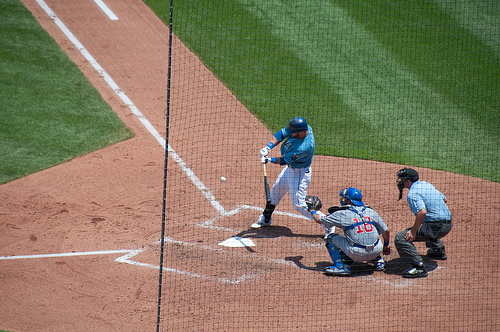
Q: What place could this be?
A: It is a field.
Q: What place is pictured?
A: It is a field.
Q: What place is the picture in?
A: It is at the field.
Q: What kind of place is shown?
A: It is a field.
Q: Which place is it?
A: It is a field.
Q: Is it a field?
A: Yes, it is a field.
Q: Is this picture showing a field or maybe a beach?
A: It is showing a field.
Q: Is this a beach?
A: No, it is a field.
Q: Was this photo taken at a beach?
A: No, the picture was taken in a field.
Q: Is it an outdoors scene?
A: Yes, it is outdoors.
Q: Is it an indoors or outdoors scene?
A: It is outdoors.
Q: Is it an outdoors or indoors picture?
A: It is outdoors.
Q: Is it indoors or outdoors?
A: It is outdoors.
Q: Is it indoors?
A: No, it is outdoors.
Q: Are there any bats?
A: Yes, there is a bat.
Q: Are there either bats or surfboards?
A: Yes, there is a bat.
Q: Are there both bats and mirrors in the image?
A: No, there is a bat but no mirrors.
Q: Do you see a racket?
A: No, there are no rackets.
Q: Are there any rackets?
A: No, there are no rackets.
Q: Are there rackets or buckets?
A: No, there are no rackets or buckets.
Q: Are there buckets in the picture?
A: No, there are no buckets.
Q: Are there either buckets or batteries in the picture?
A: No, there are no buckets or batteries.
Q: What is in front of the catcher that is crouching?
A: The home plate is in front of the catcher.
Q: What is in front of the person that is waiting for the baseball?
A: The home plate is in front of the catcher.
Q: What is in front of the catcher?
A: The home plate is in front of the catcher.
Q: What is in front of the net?
A: The home plate is in front of the net.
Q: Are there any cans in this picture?
A: No, there are no cans.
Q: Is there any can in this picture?
A: No, there are no cans.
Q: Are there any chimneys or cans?
A: No, there are no cans or chimneys.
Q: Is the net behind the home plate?
A: Yes, the net is behind the home plate.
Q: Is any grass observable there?
A: Yes, there is grass.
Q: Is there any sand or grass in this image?
A: Yes, there is grass.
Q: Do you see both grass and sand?
A: No, there is grass but no sand.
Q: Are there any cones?
A: No, there are no cones.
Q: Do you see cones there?
A: No, there are no cones.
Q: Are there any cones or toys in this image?
A: No, there are no cones or toys.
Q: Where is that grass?
A: The grass is in the field.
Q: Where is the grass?
A: The grass is in the field.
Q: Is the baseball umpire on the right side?
A: Yes, the umpire is on the right of the image.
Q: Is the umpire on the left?
A: No, the umpire is on the right of the image.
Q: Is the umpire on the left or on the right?
A: The umpire is on the right of the image.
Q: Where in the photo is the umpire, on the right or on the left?
A: The umpire is on the right of the image.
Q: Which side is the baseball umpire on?
A: The umpire is on the right of the image.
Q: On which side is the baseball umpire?
A: The umpire is on the right of the image.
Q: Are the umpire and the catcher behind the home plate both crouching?
A: Yes, both the umpire and the catcher are crouching.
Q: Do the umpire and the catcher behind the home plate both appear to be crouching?
A: Yes, both the umpire and the catcher are crouching.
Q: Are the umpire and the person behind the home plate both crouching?
A: Yes, both the umpire and the catcher are crouching.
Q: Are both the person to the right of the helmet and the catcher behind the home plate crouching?
A: Yes, both the umpire and the catcher are crouching.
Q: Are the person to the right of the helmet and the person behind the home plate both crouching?
A: Yes, both the umpire and the catcher are crouching.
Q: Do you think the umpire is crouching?
A: Yes, the umpire is crouching.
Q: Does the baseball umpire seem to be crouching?
A: Yes, the umpire is crouching.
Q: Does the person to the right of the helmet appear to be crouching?
A: Yes, the umpire is crouching.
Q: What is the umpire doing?
A: The umpire is crouching.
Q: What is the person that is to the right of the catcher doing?
A: The umpire is crouching.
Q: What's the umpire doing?
A: The umpire is crouching.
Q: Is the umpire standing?
A: No, the umpire is crouching.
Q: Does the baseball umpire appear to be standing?
A: No, the umpire is crouching.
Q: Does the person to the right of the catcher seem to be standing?
A: No, the umpire is crouching.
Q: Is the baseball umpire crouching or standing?
A: The umpire is crouching.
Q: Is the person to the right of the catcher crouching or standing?
A: The umpire is crouching.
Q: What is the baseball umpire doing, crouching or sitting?
A: The umpire is crouching.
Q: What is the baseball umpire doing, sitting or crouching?
A: The umpire is crouching.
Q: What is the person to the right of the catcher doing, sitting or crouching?
A: The umpire is crouching.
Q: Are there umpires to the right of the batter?
A: Yes, there is an umpire to the right of the batter.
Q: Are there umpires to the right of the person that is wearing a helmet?
A: Yes, there is an umpire to the right of the batter.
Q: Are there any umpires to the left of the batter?
A: No, the umpire is to the right of the batter.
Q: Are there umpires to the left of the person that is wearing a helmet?
A: No, the umpire is to the right of the batter.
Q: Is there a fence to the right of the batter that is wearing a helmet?
A: No, there is an umpire to the right of the batter.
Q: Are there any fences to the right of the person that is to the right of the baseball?
A: No, there is an umpire to the right of the batter.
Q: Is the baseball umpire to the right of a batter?
A: Yes, the umpire is to the right of a batter.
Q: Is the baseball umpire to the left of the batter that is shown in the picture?
A: No, the umpire is to the right of the batter.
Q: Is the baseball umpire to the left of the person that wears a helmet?
A: No, the umpire is to the right of the batter.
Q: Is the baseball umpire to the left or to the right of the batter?
A: The umpire is to the right of the batter.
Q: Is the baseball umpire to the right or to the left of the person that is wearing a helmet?
A: The umpire is to the right of the batter.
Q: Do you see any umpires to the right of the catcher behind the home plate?
A: Yes, there is an umpire to the right of the catcher.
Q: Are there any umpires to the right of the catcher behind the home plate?
A: Yes, there is an umpire to the right of the catcher.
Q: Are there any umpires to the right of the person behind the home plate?
A: Yes, there is an umpire to the right of the catcher.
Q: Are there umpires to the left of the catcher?
A: No, the umpire is to the right of the catcher.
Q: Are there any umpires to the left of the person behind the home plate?
A: No, the umpire is to the right of the catcher.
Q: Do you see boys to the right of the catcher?
A: No, there is an umpire to the right of the catcher.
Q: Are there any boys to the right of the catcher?
A: No, there is an umpire to the right of the catcher.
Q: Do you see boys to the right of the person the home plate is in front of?
A: No, there is an umpire to the right of the catcher.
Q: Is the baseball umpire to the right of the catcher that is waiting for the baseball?
A: Yes, the umpire is to the right of the catcher.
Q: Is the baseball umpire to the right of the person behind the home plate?
A: Yes, the umpire is to the right of the catcher.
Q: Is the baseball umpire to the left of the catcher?
A: No, the umpire is to the right of the catcher.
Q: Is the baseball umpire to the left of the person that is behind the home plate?
A: No, the umpire is to the right of the catcher.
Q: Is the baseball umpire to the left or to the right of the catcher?
A: The umpire is to the right of the catcher.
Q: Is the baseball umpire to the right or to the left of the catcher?
A: The umpire is to the right of the catcher.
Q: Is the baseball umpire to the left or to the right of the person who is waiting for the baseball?
A: The umpire is to the right of the catcher.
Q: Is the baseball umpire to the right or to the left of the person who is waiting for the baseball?
A: The umpire is to the right of the catcher.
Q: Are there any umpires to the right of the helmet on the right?
A: Yes, there is an umpire to the right of the helmet.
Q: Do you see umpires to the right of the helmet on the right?
A: Yes, there is an umpire to the right of the helmet.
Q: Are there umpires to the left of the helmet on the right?
A: No, the umpire is to the right of the helmet.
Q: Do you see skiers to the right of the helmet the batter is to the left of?
A: No, there is an umpire to the right of the helmet.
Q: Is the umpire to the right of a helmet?
A: Yes, the umpire is to the right of a helmet.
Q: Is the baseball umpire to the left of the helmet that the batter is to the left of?
A: No, the umpire is to the right of the helmet.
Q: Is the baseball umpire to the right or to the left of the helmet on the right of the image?
A: The umpire is to the right of the helmet.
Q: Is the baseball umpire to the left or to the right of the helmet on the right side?
A: The umpire is to the right of the helmet.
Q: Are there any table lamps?
A: No, there are no table lamps.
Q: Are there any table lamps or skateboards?
A: No, there are no table lamps or skateboards.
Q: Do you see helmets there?
A: Yes, there is a helmet.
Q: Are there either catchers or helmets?
A: Yes, there is a helmet.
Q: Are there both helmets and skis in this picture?
A: No, there is a helmet but no skis.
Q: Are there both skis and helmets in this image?
A: No, there is a helmet but no skis.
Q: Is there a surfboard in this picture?
A: No, there are no surfboards.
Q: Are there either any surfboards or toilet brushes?
A: No, there are no surfboards or toilet brushes.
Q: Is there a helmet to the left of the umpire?
A: Yes, there is a helmet to the left of the umpire.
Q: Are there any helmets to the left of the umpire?
A: Yes, there is a helmet to the left of the umpire.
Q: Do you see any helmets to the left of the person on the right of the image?
A: Yes, there is a helmet to the left of the umpire.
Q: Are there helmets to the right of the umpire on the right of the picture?
A: No, the helmet is to the left of the umpire.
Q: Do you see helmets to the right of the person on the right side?
A: No, the helmet is to the left of the umpire.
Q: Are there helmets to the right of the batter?
A: Yes, there is a helmet to the right of the batter.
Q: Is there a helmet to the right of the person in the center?
A: Yes, there is a helmet to the right of the batter.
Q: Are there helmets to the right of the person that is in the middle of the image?
A: Yes, there is a helmet to the right of the batter.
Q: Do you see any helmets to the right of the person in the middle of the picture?
A: Yes, there is a helmet to the right of the batter.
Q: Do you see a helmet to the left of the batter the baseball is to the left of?
A: No, the helmet is to the right of the batter.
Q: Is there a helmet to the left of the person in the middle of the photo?
A: No, the helmet is to the right of the batter.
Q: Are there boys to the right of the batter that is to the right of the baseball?
A: No, there is a helmet to the right of the batter.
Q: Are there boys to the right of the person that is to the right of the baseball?
A: No, there is a helmet to the right of the batter.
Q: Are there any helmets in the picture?
A: Yes, there is a helmet.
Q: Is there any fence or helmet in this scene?
A: Yes, there is a helmet.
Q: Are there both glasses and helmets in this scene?
A: No, there is a helmet but no glasses.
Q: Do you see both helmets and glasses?
A: No, there is a helmet but no glasses.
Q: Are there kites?
A: No, there are no kites.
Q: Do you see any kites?
A: No, there are no kites.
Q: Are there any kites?
A: No, there are no kites.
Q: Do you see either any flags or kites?
A: No, there are no kites or flags.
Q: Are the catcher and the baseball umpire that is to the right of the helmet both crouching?
A: Yes, both the catcher and the umpire are crouching.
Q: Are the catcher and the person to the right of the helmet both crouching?
A: Yes, both the catcher and the umpire are crouching.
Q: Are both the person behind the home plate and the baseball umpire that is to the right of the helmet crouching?
A: Yes, both the catcher and the umpire are crouching.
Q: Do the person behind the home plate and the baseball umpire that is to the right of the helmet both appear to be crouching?
A: Yes, both the catcher and the umpire are crouching.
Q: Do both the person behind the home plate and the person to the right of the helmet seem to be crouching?
A: Yes, both the catcher and the umpire are crouching.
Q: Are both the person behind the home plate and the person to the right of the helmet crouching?
A: Yes, both the catcher and the umpire are crouching.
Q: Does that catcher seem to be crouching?
A: Yes, the catcher is crouching.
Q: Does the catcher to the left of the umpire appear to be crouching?
A: Yes, the catcher is crouching.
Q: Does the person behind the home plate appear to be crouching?
A: Yes, the catcher is crouching.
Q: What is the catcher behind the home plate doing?
A: The catcher is crouching.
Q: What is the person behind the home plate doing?
A: The catcher is crouching.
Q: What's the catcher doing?
A: The catcher is crouching.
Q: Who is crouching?
A: The catcher is crouching.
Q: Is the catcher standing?
A: No, the catcher is crouching.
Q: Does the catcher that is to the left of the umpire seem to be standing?
A: No, the catcher is crouching.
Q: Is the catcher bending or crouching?
A: The catcher is crouching.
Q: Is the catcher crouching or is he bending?
A: The catcher is crouching.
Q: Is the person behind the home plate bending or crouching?
A: The catcher is crouching.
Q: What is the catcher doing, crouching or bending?
A: The catcher is crouching.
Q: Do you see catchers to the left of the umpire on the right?
A: Yes, there is a catcher to the left of the umpire.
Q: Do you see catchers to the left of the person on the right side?
A: Yes, there is a catcher to the left of the umpire.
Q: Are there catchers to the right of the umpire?
A: No, the catcher is to the left of the umpire.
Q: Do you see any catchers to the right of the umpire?
A: No, the catcher is to the left of the umpire.